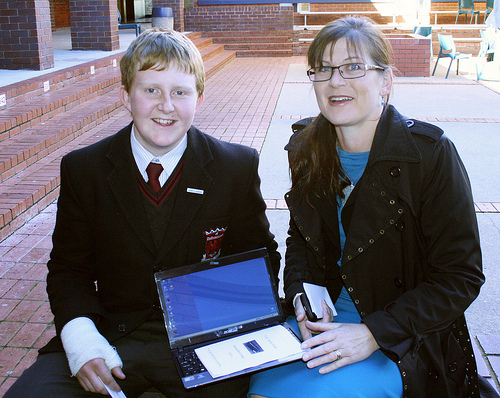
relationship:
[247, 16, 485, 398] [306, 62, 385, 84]
woman wearing glasses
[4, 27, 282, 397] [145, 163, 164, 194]
boy wearing tie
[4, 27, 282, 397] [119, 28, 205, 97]
boy has hair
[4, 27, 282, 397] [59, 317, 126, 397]
boy has hand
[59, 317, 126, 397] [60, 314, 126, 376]
hand covered by cast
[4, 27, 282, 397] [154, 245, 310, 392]
boy holding laptop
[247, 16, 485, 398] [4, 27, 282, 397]
woman sitting by boy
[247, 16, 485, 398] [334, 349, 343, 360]
woman wearing ring finger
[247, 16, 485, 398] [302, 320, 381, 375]
woman has hand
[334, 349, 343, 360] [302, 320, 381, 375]
ring finger worn on hand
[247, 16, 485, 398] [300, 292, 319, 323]
woman holding cell phone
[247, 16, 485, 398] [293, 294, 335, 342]
woman has hand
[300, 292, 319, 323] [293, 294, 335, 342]
cell phone held in hand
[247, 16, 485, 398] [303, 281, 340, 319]
woman holding envelope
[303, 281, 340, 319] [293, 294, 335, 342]
envelope held in hand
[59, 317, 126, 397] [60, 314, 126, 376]
hand has cast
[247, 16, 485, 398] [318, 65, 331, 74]
woman has eye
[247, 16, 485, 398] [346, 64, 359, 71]
woman has eye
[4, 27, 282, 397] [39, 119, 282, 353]
boy wears coat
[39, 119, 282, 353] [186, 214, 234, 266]
coat has pocket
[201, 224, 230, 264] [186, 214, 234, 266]
insignia sewn on pocket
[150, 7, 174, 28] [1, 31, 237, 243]
trash can sitting at top of steps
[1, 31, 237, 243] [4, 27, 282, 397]
steps behind boy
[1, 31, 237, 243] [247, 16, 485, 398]
steps behind woman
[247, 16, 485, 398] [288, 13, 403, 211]
woman has hair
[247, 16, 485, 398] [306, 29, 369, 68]
woman has bangs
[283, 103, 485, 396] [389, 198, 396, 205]
jacket has eyelet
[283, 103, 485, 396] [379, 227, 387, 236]
jacket has eyelet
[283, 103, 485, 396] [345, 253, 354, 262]
jacket has eyelet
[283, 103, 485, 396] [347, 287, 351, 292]
jacket has eyelet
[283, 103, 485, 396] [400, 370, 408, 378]
jacket has eyelet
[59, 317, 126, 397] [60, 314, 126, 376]
hand wrapped in cast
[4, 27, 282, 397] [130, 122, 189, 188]
boy wearing shirt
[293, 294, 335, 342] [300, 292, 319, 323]
hand holding cell phone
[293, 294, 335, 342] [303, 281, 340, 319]
hand holding envelope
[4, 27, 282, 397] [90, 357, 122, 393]
boy has finger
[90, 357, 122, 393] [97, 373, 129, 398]
finger has splint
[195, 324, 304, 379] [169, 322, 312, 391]
pamphlet on top of keyboard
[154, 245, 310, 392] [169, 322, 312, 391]
laptop has keyboard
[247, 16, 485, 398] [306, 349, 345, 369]
woman has ring finger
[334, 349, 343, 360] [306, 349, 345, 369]
ring finger worn on ring finger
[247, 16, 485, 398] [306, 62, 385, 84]
woman wears glasses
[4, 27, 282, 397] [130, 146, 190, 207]
boy wears vest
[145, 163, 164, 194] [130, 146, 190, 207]
tie tucked into vest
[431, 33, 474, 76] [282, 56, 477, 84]
patio chair sitting on cement